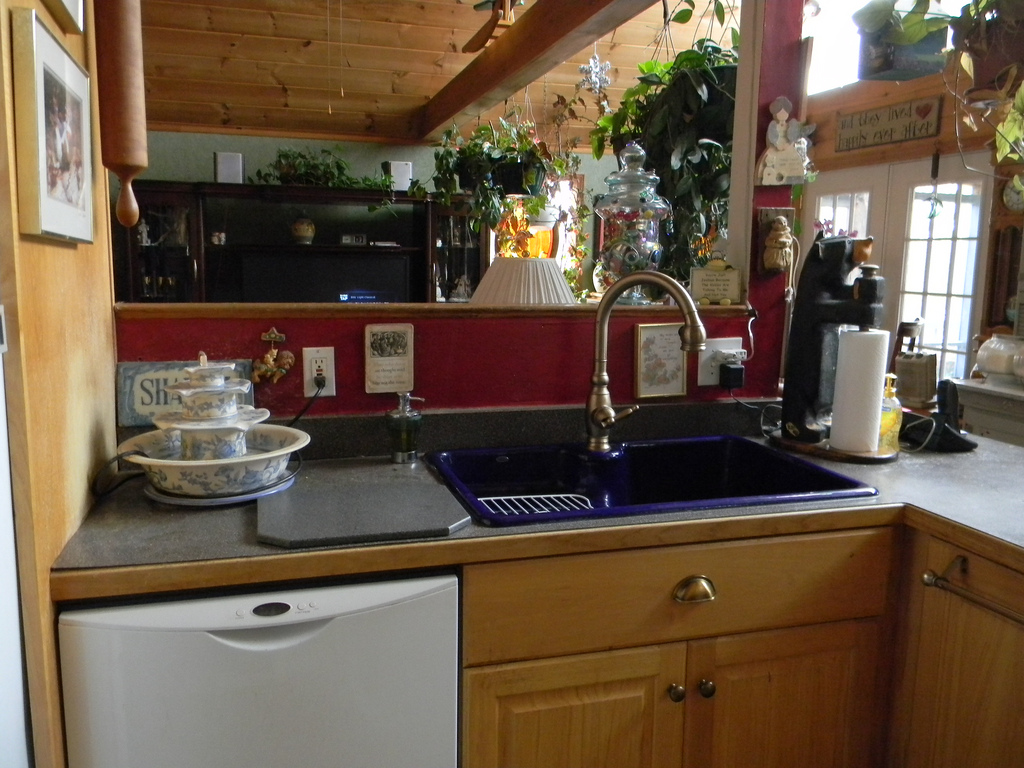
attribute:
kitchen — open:
[7, 2, 1023, 750]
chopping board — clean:
[267, 451, 471, 546]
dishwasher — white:
[48, 565, 463, 765]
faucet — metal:
[586, 261, 719, 455]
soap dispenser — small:
[384, 382, 430, 463]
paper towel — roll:
[827, 323, 891, 456]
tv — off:
[219, 239, 419, 296]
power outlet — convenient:
[298, 343, 338, 400]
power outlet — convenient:
[696, 334, 741, 391]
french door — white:
[877, 139, 1005, 390]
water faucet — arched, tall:
[586, 262, 704, 428]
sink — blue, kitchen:
[435, 432, 879, 519]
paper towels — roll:
[838, 329, 887, 451]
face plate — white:
[302, 340, 341, 395]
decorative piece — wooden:
[760, 97, 814, 189]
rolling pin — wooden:
[78, 5, 149, 236]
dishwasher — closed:
[59, 581, 462, 765]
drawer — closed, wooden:
[465, 517, 905, 677]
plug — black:
[311, 372, 328, 393]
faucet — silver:
[589, 271, 703, 452]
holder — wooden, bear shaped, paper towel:
[769, 215, 905, 469]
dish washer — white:
[49, 583, 468, 762]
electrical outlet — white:
[299, 346, 337, 405]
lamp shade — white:
[463, 250, 578, 311]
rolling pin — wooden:
[81, 0, 158, 229]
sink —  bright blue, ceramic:
[418, 406, 891, 537]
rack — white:
[471, 477, 601, 531]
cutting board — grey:
[247, 443, 489, 557]